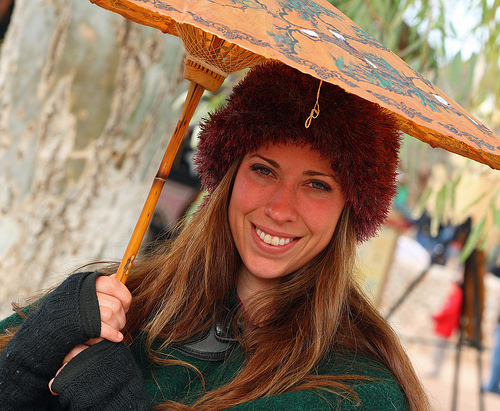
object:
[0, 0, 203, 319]
tree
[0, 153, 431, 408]
hair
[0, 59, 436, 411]
lady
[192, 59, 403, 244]
hat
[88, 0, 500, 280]
umbrella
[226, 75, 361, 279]
head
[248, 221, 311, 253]
smile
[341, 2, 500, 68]
leaves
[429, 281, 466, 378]
person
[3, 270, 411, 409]
coat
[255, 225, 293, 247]
teeth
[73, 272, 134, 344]
hand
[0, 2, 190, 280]
bark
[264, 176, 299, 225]
nose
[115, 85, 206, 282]
pole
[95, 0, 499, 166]
top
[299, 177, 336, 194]
eyes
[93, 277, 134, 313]
fingers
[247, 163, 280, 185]
eye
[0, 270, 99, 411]
sleeves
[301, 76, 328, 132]
string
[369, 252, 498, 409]
sidewalk